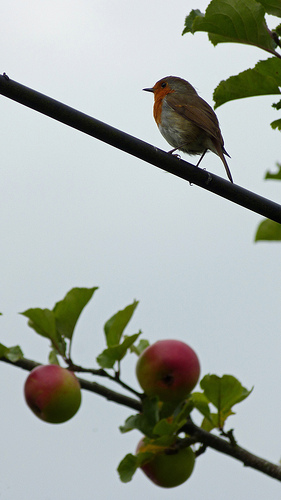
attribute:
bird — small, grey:
[137, 65, 237, 212]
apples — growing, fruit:
[23, 330, 201, 489]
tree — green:
[2, 3, 279, 500]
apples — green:
[135, 429, 203, 491]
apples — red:
[21, 341, 200, 427]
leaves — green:
[1, 266, 269, 484]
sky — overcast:
[12, 3, 167, 61]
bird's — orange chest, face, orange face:
[140, 73, 175, 102]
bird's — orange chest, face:
[151, 98, 168, 128]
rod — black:
[0, 63, 280, 243]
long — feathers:
[165, 90, 231, 157]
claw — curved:
[139, 133, 225, 204]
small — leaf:
[110, 445, 160, 486]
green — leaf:
[96, 329, 148, 367]